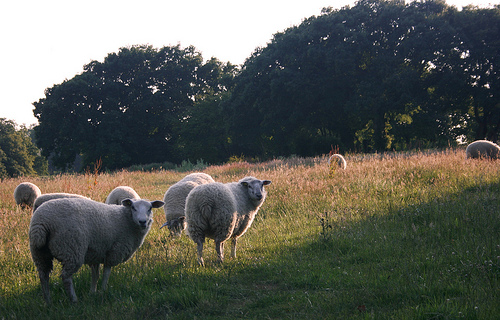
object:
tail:
[28, 221, 50, 252]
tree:
[224, 0, 495, 161]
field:
[0, 147, 500, 320]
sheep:
[11, 180, 43, 210]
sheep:
[29, 198, 166, 306]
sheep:
[158, 171, 219, 241]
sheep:
[183, 176, 273, 269]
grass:
[376, 184, 500, 319]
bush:
[122, 159, 190, 172]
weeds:
[173, 157, 208, 172]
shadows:
[0, 178, 499, 318]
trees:
[0, 0, 499, 174]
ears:
[261, 179, 273, 186]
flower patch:
[317, 211, 333, 247]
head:
[241, 178, 272, 203]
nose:
[255, 192, 263, 198]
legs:
[31, 254, 58, 304]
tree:
[0, 115, 51, 180]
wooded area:
[1, 0, 500, 181]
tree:
[31, 41, 242, 167]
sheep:
[33, 191, 84, 219]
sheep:
[104, 183, 141, 207]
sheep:
[327, 153, 348, 174]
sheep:
[462, 139, 500, 163]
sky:
[1, 0, 500, 133]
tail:
[199, 201, 216, 223]